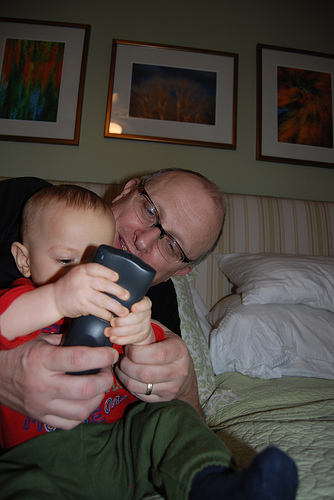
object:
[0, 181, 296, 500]
baby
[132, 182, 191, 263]
glasses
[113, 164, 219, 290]
face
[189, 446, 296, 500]
blue sock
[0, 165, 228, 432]
man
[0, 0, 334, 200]
pictures wall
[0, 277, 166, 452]
red shirt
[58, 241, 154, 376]
remote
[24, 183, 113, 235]
hair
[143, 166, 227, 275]
hair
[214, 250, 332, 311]
pillow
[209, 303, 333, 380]
pillow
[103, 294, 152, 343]
hand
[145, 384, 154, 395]
ring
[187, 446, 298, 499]
socks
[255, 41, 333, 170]
picture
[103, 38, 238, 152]
picture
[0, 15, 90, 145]
picture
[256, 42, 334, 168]
frame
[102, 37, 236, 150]
frame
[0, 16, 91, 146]
frame